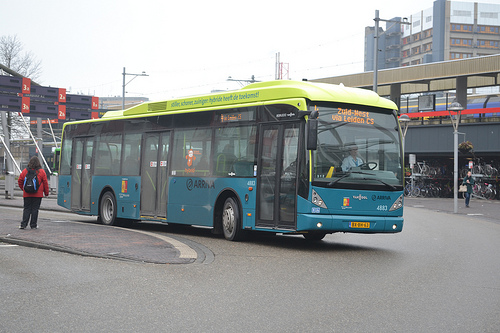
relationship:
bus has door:
[53, 77, 409, 242] [69, 135, 101, 216]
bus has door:
[53, 77, 409, 242] [139, 126, 177, 219]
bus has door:
[53, 77, 409, 242] [255, 121, 303, 232]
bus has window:
[53, 77, 409, 242] [90, 130, 126, 175]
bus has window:
[53, 77, 409, 242] [168, 125, 217, 178]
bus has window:
[53, 77, 409, 242] [210, 124, 258, 178]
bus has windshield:
[53, 77, 409, 242] [310, 103, 403, 193]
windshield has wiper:
[310, 103, 403, 193] [363, 175, 400, 193]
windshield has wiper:
[310, 103, 403, 193] [325, 164, 379, 188]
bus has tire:
[53, 77, 409, 242] [96, 188, 121, 227]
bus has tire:
[53, 77, 409, 242] [217, 193, 245, 242]